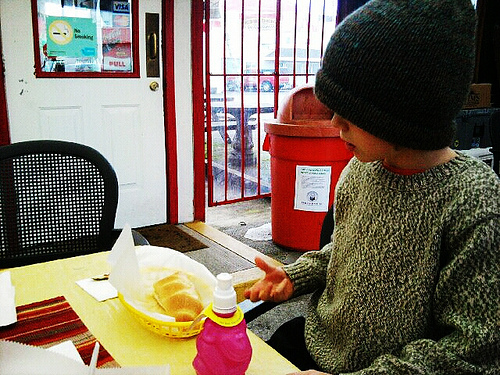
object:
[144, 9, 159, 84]
handle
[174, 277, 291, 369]
bottle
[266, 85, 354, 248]
trash can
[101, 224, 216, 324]
paper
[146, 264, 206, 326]
sandwich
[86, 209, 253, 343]
basket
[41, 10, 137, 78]
stickers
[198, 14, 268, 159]
gate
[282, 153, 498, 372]
sweater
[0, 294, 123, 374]
mat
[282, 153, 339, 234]
label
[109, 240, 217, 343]
train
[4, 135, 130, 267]
chair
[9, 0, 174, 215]
door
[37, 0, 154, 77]
signs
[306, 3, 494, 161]
hat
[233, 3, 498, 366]
child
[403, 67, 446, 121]
ground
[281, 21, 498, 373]
boy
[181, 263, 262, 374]
container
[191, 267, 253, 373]
pink bottle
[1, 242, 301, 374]
table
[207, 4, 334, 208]
bars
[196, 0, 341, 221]
door